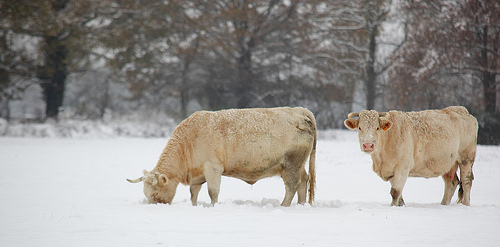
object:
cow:
[129, 105, 322, 211]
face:
[143, 179, 161, 206]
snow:
[1, 137, 497, 247]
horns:
[150, 173, 161, 182]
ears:
[342, 117, 359, 130]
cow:
[348, 106, 478, 210]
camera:
[0, 0, 499, 247]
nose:
[363, 143, 375, 149]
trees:
[374, 0, 500, 123]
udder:
[446, 164, 456, 179]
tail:
[306, 112, 319, 207]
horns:
[346, 111, 361, 119]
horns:
[125, 177, 144, 184]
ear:
[158, 174, 170, 186]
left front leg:
[200, 165, 226, 209]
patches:
[460, 156, 470, 167]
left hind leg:
[454, 146, 478, 208]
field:
[2, 97, 498, 246]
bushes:
[1, 119, 47, 139]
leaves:
[462, 0, 498, 29]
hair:
[185, 121, 289, 149]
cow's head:
[124, 167, 178, 205]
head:
[347, 106, 392, 155]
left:
[0, 92, 128, 247]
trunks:
[37, 51, 66, 118]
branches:
[63, 43, 142, 74]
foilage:
[58, 112, 177, 128]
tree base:
[41, 106, 66, 125]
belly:
[225, 137, 288, 182]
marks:
[254, 158, 281, 173]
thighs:
[283, 148, 307, 177]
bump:
[281, 106, 305, 111]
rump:
[282, 103, 320, 156]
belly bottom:
[409, 166, 464, 180]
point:
[449, 153, 455, 159]